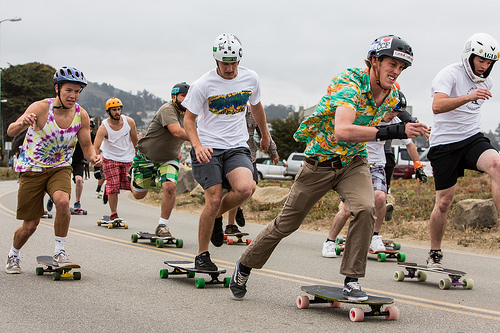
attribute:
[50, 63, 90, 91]
helmet — blue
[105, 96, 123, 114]
helmet — orange, yellow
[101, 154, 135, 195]
shorts — plaid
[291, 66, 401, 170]
shirt — green, yellow, blowing in wind, hawaiian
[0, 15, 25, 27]
streetlight — white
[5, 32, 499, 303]
guys — grouped, racing, skateboarding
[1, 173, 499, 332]
road — open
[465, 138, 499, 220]
leg — in the air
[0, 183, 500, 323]
stripes — yellow paint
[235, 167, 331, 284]
leg — extended back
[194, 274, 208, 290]
wheel — green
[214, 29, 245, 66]
helmet — white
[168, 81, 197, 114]
helmet — black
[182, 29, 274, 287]
man — skateboarding